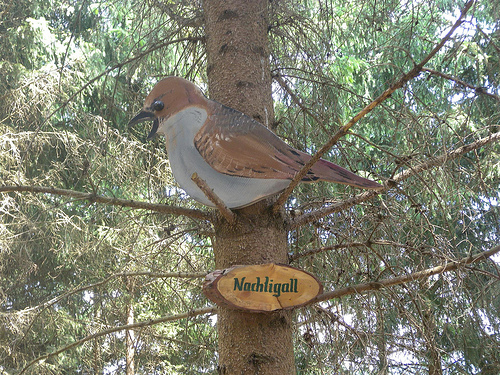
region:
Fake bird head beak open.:
[121, 62, 217, 152]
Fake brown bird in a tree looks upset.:
[114, 48, 387, 243]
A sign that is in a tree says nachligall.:
[200, 236, 340, 330]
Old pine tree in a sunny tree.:
[361, 33, 493, 296]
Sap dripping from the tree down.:
[210, 14, 280, 94]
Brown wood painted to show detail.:
[205, 117, 262, 167]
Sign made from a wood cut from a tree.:
[189, 248, 330, 334]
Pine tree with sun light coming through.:
[2, 15, 154, 212]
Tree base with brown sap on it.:
[190, 324, 348, 374]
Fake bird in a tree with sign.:
[82, 26, 429, 367]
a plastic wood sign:
[191, 247, 336, 326]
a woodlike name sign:
[191, 246, 339, 331]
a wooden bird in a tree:
[129, 63, 389, 222]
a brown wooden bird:
[113, 37, 398, 251]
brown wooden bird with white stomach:
[114, 28, 394, 240]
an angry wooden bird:
[112, 60, 394, 240]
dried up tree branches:
[17, 108, 205, 340]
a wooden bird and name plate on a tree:
[124, 52, 426, 352]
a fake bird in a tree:
[110, 45, 400, 240]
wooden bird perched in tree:
[122, 58, 394, 240]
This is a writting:
[184, 241, 356, 346]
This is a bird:
[102, 51, 394, 219]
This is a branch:
[298, 249, 493, 289]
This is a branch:
[328, 141, 489, 199]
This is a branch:
[50, 299, 204, 370]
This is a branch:
[7, 259, 199, 319]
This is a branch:
[22, 168, 190, 212]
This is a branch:
[280, 53, 401, 165]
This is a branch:
[28, 25, 195, 145]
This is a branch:
[31, 103, 173, 160]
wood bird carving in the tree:
[118, 75, 334, 217]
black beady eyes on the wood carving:
[146, 96, 168, 128]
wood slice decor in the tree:
[191, 240, 340, 325]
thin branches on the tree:
[8, 83, 489, 355]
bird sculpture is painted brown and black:
[168, 80, 306, 203]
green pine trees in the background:
[16, 15, 497, 370]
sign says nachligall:
[193, 262, 328, 321]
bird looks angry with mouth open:
[114, 96, 169, 156]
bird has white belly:
[159, 109, 268, 226]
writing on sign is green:
[226, 259, 341, 342]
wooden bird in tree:
[124, 82, 286, 202]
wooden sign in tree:
[196, 274, 378, 371]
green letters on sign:
[234, 270, 322, 300]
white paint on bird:
[169, 119, 249, 199]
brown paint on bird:
[203, 114, 273, 162]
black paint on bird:
[134, 114, 161, 136]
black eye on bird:
[150, 91, 167, 113]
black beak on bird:
[116, 113, 199, 154]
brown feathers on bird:
[236, 137, 316, 177]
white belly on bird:
[179, 157, 245, 205]